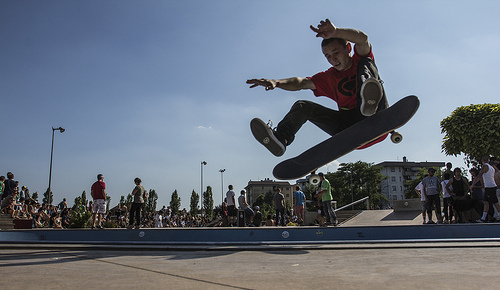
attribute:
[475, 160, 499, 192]
top — white, tank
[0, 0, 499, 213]
sky — blue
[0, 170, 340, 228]
people — large group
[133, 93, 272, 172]
clouds — white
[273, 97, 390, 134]
jeans — black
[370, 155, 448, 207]
house — white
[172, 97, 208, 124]
clouds — white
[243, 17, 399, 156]
man — young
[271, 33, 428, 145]
shirt — red, short sleeve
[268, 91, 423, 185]
skateboard — black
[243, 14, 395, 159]
skateboarder — white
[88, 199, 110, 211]
knee — knee length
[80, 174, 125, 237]
man — in red, in white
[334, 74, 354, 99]
symbol — black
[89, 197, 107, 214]
shorts — white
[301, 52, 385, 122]
t-shirt — red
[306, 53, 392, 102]
shirt — red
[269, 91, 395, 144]
jeans — black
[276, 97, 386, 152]
jeans — black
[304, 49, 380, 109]
shirt — red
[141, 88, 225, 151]
cloud — white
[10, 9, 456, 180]
sky — blue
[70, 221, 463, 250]
wall — low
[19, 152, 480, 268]
park — skate